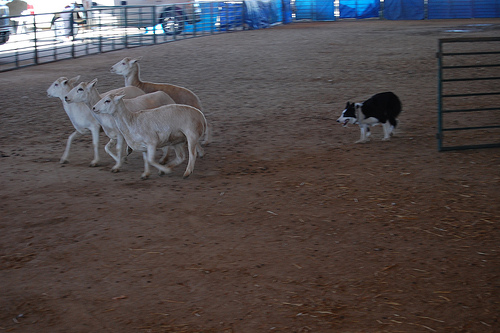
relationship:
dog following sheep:
[336, 89, 402, 142] [95, 94, 204, 178]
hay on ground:
[312, 306, 335, 317] [0, 23, 495, 331]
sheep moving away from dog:
[65, 78, 99, 106] [336, 89, 402, 142]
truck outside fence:
[78, 1, 202, 38] [0, 0, 499, 76]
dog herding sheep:
[336, 89, 402, 142] [95, 94, 204, 178]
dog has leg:
[336, 89, 402, 142] [360, 123, 366, 140]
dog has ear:
[336, 89, 402, 142] [352, 100, 358, 110]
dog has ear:
[335, 92, 402, 144] [344, 100, 352, 110]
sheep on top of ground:
[95, 94, 204, 178] [0, 23, 495, 331]